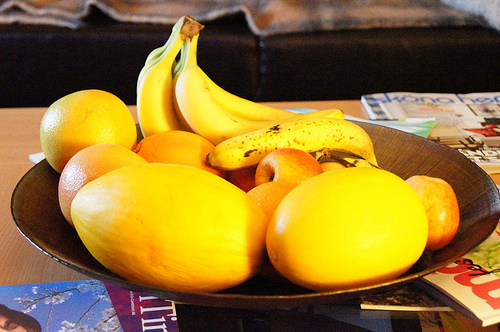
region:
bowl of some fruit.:
[10, 25, 492, 305]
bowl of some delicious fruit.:
[15, 10, 491, 289]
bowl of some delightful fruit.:
[19, 26, 485, 303]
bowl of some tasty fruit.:
[12, 11, 487, 298]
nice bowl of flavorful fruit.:
[24, 31, 486, 282]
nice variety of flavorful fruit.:
[13, 11, 485, 302]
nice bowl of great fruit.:
[17, 13, 488, 306]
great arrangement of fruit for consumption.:
[20, 21, 488, 299]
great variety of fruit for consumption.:
[13, 19, 483, 311]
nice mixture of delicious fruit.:
[17, 14, 484, 296]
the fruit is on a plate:
[39, 16, 457, 294]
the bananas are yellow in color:
[134, 17, 330, 144]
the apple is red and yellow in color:
[253, 148, 321, 192]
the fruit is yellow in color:
[42, 87, 137, 174]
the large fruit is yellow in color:
[70, 162, 266, 290]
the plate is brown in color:
[16, 112, 498, 306]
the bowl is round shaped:
[10, 116, 490, 309]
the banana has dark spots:
[267, 121, 279, 133]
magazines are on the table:
[361, 90, 497, 171]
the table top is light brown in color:
[3, 98, 482, 328]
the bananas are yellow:
[118, 17, 381, 170]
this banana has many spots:
[206, 108, 375, 171]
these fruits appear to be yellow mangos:
[68, 142, 427, 291]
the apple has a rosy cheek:
[236, 115, 343, 189]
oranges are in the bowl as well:
[50, 127, 220, 233]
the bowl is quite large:
[8, 130, 499, 296]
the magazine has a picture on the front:
[0, 279, 187, 329]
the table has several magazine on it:
[364, 82, 497, 325]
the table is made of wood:
[8, 113, 37, 145]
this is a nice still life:
[8, 12, 498, 312]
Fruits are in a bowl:
[5, 13, 498, 325]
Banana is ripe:
[193, 111, 388, 173]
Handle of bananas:
[130, 4, 348, 152]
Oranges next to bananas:
[26, 86, 224, 207]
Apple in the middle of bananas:
[246, 143, 323, 193]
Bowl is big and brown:
[6, 103, 498, 322]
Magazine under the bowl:
[418, 230, 496, 328]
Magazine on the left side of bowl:
[1, 270, 207, 329]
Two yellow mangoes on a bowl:
[62, 151, 439, 292]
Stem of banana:
[161, 14, 209, 49]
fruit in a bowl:
[16, 37, 453, 327]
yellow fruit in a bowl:
[25, 47, 446, 307]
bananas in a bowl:
[120, 26, 395, 157]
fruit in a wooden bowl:
[34, 56, 477, 318]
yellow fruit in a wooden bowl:
[2, 64, 465, 304]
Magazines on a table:
[341, 72, 498, 197]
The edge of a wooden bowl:
[377, 115, 498, 288]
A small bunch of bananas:
[128, 14, 328, 141]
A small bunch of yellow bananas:
[131, 19, 349, 152]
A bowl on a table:
[20, 71, 483, 330]